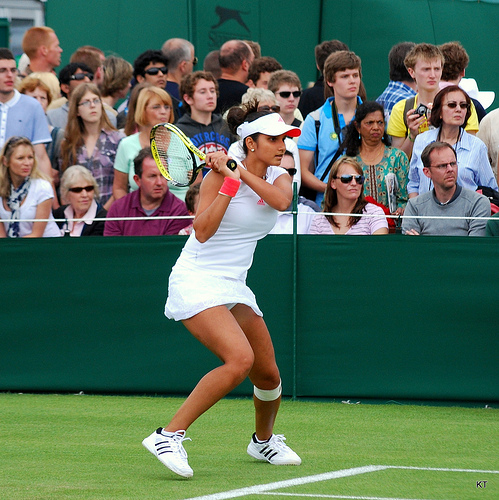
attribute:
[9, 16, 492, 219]
people — standing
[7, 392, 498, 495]
tennis court — green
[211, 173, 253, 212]
wristband — red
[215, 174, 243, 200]
wristband — red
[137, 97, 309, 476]
tennis player — female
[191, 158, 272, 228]
wristband — red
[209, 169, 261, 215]
wristband — red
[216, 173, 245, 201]
wristband — red, on player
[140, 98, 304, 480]
player — tennis, female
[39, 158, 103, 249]
woman — old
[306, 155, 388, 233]
spectator — watching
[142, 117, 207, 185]
racket — black, yellow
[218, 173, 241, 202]
wristband — Red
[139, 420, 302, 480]
pins — white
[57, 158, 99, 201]
hair — gray